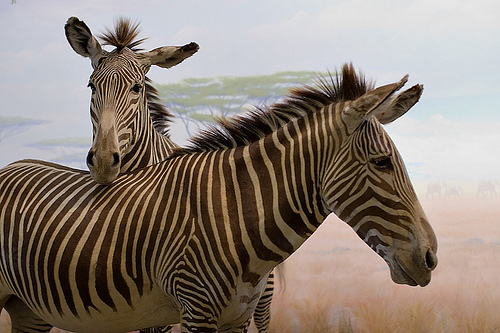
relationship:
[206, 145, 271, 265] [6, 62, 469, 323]
stripes on zebra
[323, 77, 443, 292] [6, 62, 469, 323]
face of zebra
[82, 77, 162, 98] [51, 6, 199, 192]
eyes of zebra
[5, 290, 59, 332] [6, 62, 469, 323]
leg of zebra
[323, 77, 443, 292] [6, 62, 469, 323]
head of zebra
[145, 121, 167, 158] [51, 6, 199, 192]
stripes on zebra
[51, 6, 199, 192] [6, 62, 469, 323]
zebra behind zebra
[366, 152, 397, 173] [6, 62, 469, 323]
eye of zebra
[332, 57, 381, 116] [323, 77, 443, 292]
hair on head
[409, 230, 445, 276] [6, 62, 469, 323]
nose on zebra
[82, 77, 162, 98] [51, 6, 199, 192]
eyes on zebra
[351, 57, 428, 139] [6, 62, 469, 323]
ears on zebra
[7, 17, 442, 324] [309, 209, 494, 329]
zebras are in a field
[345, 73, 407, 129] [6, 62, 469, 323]
ear of zebra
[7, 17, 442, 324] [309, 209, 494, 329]
zebras in field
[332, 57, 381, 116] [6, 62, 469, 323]
hair on zebra